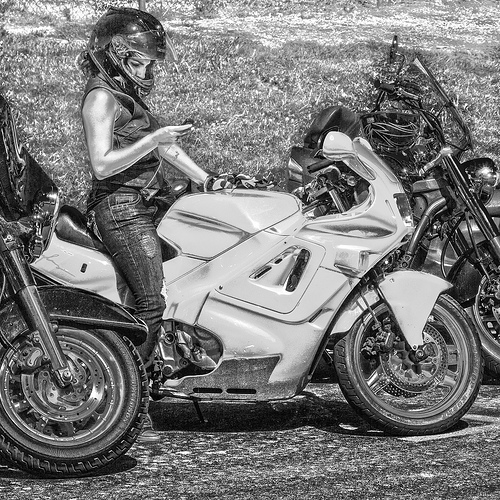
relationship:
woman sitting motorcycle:
[63, 7, 222, 392] [3, 97, 484, 475]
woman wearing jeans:
[63, 7, 225, 393] [85, 169, 177, 374]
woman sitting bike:
[63, 7, 225, 393] [26, 105, 481, 438]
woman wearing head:
[63, 7, 225, 393] [74, 3, 167, 102]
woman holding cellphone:
[63, 7, 225, 393] [166, 105, 210, 140]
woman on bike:
[63, 7, 225, 393] [0, 82, 457, 409]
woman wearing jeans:
[63, 7, 225, 393] [87, 190, 170, 366]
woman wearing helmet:
[63, 7, 225, 393] [79, 1, 169, 99]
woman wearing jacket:
[63, 7, 225, 393] [80, 71, 170, 201]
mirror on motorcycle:
[320, 129, 355, 164] [20, 127, 487, 435]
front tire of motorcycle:
[0, 335, 150, 473] [0, 146, 148, 476]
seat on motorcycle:
[54, 204, 109, 254] [20, 127, 487, 435]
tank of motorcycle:
[143, 167, 308, 259] [3, 97, 484, 475]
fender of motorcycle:
[378, 267, 455, 351] [20, 127, 487, 435]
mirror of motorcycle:
[320, 129, 356, 164] [3, 97, 484, 475]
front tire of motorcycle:
[0, 320, 152, 472] [3, 97, 484, 475]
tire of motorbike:
[344, 276, 484, 428] [7, 113, 474, 484]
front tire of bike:
[0, 320, 152, 472] [26, 105, 481, 438]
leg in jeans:
[94, 177, 174, 385] [86, 184, 168, 367]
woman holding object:
[63, 7, 225, 393] [177, 110, 194, 138]